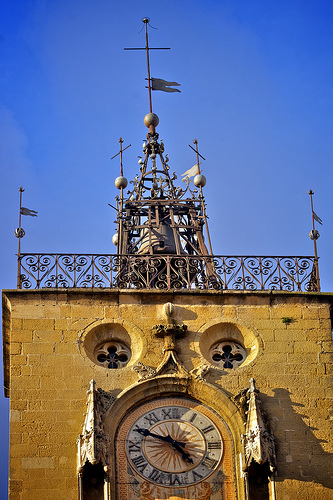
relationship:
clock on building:
[98, 360, 285, 483] [28, 61, 326, 495]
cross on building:
[188, 324, 268, 382] [28, 61, 326, 495]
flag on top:
[132, 49, 199, 107] [83, 27, 236, 176]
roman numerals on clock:
[119, 398, 227, 484] [98, 360, 285, 483]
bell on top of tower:
[117, 187, 209, 280] [72, 86, 229, 287]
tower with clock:
[72, 86, 229, 287] [80, 369, 254, 479]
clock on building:
[98, 360, 285, 483] [7, 220, 323, 492]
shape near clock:
[249, 381, 274, 475] [98, 360, 285, 483]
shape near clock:
[76, 379, 113, 472] [98, 360, 285, 483]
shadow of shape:
[243, 367, 317, 488] [249, 381, 274, 475]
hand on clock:
[163, 431, 193, 462] [98, 360, 285, 483]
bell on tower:
[131, 213, 196, 286] [72, 86, 229, 287]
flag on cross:
[132, 49, 199, 107] [116, 14, 180, 79]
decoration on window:
[149, 302, 190, 378] [185, 305, 277, 383]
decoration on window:
[149, 302, 190, 378] [58, 312, 145, 371]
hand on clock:
[133, 425, 187, 448] [98, 360, 285, 483]